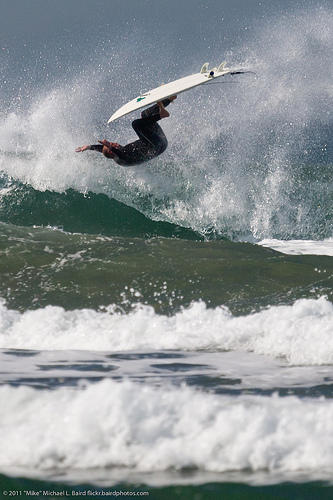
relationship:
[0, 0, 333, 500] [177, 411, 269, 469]
water on waves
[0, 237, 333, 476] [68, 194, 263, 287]
foam on water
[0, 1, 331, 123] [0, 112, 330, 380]
sky above water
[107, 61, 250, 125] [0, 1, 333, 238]
surfboard falling from wave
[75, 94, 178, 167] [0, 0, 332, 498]
man surfing in ocean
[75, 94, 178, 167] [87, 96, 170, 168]
man wearing wetsuit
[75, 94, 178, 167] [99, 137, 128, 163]
man has arm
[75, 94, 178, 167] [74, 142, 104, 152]
man has arm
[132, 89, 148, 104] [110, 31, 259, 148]
design on surfboard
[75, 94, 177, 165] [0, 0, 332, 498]
man in ocean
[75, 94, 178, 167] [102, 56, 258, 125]
man on surfboard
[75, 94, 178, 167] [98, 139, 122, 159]
man has head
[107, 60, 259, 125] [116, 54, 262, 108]
surfboard has rudders